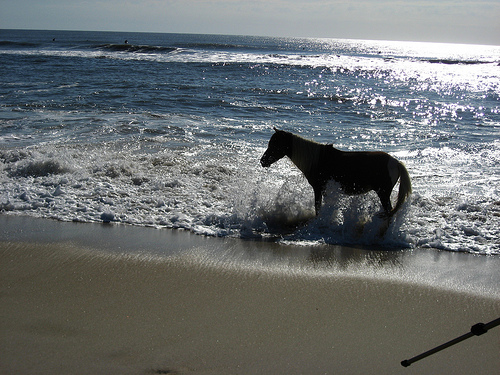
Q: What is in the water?
A: Horse.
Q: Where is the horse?
A: In the water.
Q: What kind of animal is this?
A: Horse.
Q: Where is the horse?
A: Beach.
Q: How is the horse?
A: Wet.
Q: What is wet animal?
A: Horse.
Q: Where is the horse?
A: In water.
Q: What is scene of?
A: Beach.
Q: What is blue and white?
A: Beach.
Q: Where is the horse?
A: In water.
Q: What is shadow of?
A: Object.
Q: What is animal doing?
A: Splashing.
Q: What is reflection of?
A: Water.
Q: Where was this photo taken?
A: At the beach.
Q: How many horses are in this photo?
A: One.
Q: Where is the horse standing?
A: In the water.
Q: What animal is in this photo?
A: A horse.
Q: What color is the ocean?
A: Blue.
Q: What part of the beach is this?
A: The shore.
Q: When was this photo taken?
A: Outside, during the daytime.